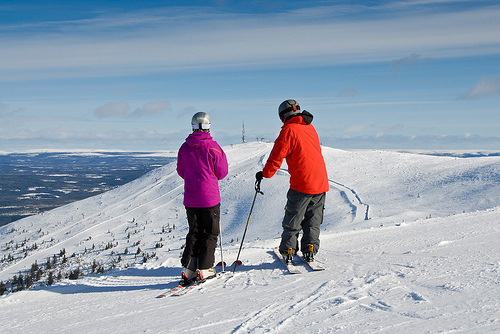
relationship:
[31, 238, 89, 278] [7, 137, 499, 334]
plants in snow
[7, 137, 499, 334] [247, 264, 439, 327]
snow has prints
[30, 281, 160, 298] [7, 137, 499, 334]
shadow on snow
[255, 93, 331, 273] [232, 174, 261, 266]
person holding stick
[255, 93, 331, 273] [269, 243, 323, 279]
person trying to skate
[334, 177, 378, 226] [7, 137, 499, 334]
mark on ice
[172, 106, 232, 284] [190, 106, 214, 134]
person wears a cap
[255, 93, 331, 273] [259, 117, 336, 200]
man wearing jacket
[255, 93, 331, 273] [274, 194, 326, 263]
man wearing pants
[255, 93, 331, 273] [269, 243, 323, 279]
man wearing skis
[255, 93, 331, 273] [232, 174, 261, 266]
man holding ski pole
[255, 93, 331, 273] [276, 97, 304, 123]
man wearing helmet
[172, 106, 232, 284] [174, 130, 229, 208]
woman wearing a jacket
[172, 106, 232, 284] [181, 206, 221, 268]
woman wearing black pants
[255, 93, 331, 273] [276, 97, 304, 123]
skier wears helmet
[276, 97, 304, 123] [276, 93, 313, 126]
helmet on head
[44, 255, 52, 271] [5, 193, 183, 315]
tree in down hill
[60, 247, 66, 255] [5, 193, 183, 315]
tree on down hill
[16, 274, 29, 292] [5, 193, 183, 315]
tree in down hill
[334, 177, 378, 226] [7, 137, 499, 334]
tracks in snow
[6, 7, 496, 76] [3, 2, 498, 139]
cloud across sky